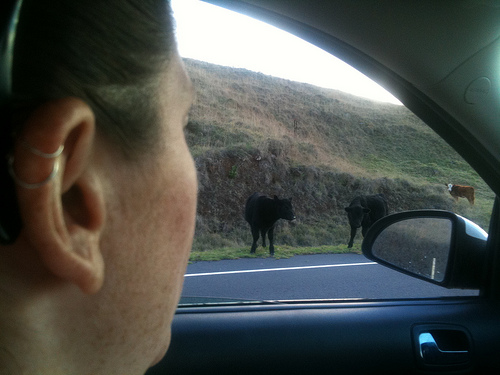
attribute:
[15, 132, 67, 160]
earring — silver, hoop, metal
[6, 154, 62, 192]
earring — silver, hoop, metal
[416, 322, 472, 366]
handle — silver, interior, inner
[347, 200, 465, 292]
mirror — side, black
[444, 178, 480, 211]
cow — brown, white, standing, red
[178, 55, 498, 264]
grass — green, dead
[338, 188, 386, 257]
cow — black, angus, young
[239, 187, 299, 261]
cow — black, angus, young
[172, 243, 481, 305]
street — gray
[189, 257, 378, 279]
line — white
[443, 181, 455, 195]
head — white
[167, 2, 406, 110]
sky — white